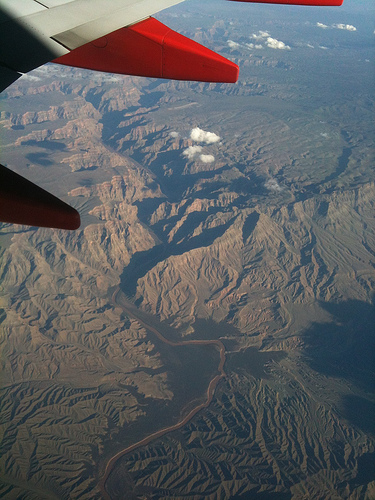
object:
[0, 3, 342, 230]
plane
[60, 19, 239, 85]
engine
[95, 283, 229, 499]
river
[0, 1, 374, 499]
sky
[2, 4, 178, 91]
wing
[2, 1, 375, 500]
mountains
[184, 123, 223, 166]
cloud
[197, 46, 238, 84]
tip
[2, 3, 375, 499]
air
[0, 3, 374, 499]
ground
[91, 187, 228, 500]
trail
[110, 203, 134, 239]
peak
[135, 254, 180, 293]
ridge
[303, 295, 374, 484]
shadow